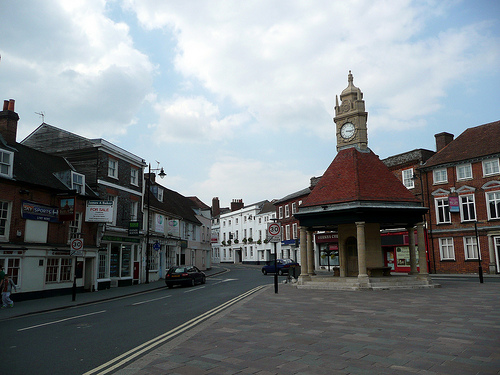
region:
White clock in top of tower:
[336, 119, 357, 142]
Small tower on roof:
[323, 61, 376, 161]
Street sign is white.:
[261, 216, 285, 248]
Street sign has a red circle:
[261, 217, 287, 247]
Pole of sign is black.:
[268, 242, 284, 297]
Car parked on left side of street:
[159, 257, 210, 291]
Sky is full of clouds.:
[14, 9, 491, 135]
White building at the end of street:
[216, 196, 281, 267]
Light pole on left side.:
[136, 153, 171, 290]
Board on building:
[80, 190, 121, 229]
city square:
[184, 271, 489, 361]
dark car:
[164, 257, 208, 291]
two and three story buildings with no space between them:
[1, 150, 213, 270]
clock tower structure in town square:
[288, 75, 438, 292]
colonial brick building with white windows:
[428, 117, 490, 287]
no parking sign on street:
[260, 210, 291, 278]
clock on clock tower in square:
[340, 118, 360, 142]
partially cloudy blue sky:
[8, 4, 480, 151]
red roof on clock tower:
[297, 144, 424, 204]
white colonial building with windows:
[210, 205, 282, 262]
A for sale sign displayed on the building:
[74, 193, 121, 226]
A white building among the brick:
[208, 186, 288, 276]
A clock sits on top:
[324, 73, 378, 164]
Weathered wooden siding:
[25, 119, 157, 229]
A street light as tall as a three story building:
[141, 158, 171, 194]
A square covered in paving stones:
[145, 290, 476, 372]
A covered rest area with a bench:
[297, 149, 450, 311]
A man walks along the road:
[1, 262, 28, 319]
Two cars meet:
[150, 241, 311, 306]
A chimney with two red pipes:
[2, 92, 33, 144]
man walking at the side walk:
[1, 266, 19, 305]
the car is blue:
[261, 255, 323, 285]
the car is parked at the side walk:
[142, 261, 228, 306]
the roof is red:
[301, 146, 421, 225]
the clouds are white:
[187, 26, 262, 150]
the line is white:
[111, 311, 183, 373]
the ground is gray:
[91, 298, 164, 355]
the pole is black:
[466, 214, 489, 281]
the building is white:
[218, 210, 279, 275]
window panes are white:
[427, 180, 491, 272]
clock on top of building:
[320, 67, 370, 150]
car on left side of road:
[157, 261, 209, 291]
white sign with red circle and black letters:
[260, 218, 285, 246]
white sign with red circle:
[63, 234, 87, 259]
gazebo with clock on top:
[283, 61, 440, 296]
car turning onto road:
[258, 256, 304, 278]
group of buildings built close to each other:
[1, 92, 218, 300]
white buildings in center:
[210, 198, 280, 263]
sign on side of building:
[442, 187, 464, 217]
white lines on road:
[12, 287, 174, 334]